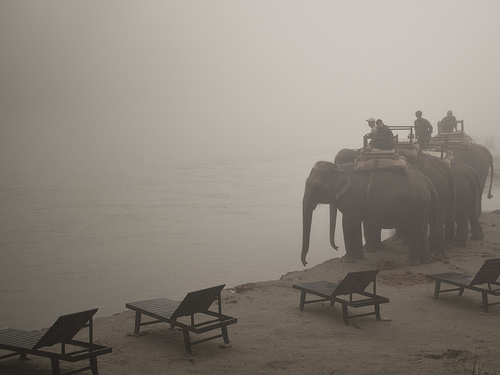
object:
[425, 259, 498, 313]
beach chair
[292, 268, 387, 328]
beach chair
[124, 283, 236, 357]
beach chair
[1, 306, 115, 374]
beach chair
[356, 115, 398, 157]
people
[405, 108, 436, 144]
people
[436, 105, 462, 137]
people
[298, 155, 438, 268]
elephants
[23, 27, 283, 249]
fog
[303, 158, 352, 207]
head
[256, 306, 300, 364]
ground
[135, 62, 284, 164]
foggy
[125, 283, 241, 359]
benches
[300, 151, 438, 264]
elephant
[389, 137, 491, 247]
elephant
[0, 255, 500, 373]
chairs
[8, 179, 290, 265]
water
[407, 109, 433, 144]
man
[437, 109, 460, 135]
man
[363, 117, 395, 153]
man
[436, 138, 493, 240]
elephant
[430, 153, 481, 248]
elephant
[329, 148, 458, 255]
elephant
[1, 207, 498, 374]
beach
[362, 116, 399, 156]
person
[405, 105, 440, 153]
person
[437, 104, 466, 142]
person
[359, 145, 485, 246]
elephant